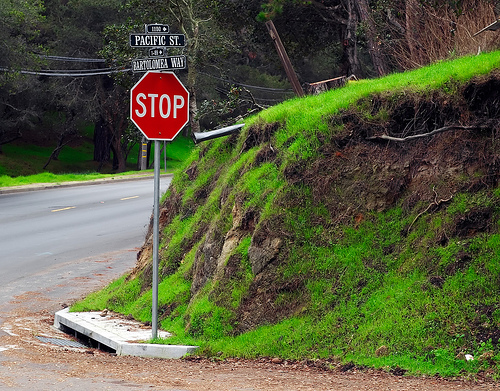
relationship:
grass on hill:
[267, 97, 357, 157] [168, 145, 481, 332]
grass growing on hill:
[235, 50, 500, 161] [64, 50, 499, 382]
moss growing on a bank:
[327, 222, 425, 305] [122, 55, 498, 369]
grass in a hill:
[235, 50, 500, 161] [266, 80, 497, 345]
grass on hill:
[235, 50, 500, 161] [242, 69, 467, 189]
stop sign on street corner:
[130, 70, 195, 147] [51, 272, 205, 367]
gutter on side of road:
[30, 288, 186, 383] [105, 332, 302, 387]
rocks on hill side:
[257, 169, 372, 274] [226, 83, 418, 286]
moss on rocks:
[229, 233, 255, 256] [257, 169, 372, 274]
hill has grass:
[64, 50, 499, 382] [235, 50, 500, 161]